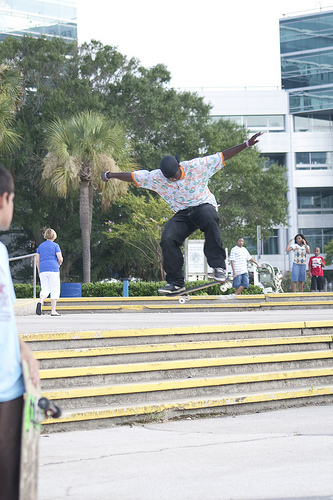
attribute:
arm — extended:
[195, 128, 270, 179]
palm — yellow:
[47, 166, 72, 198]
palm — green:
[78, 117, 118, 138]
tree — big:
[7, 37, 171, 114]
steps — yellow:
[178, 330, 274, 415]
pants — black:
[151, 202, 227, 275]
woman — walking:
[31, 226, 69, 318]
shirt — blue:
[35, 243, 63, 274]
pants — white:
[37, 273, 68, 302]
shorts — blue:
[233, 272, 254, 289]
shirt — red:
[311, 256, 329, 276]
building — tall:
[256, 4, 329, 233]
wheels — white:
[174, 282, 236, 308]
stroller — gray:
[257, 261, 286, 300]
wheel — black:
[35, 393, 64, 421]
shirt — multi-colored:
[144, 175, 226, 213]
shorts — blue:
[288, 264, 309, 285]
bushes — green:
[84, 284, 122, 297]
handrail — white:
[10, 254, 37, 265]